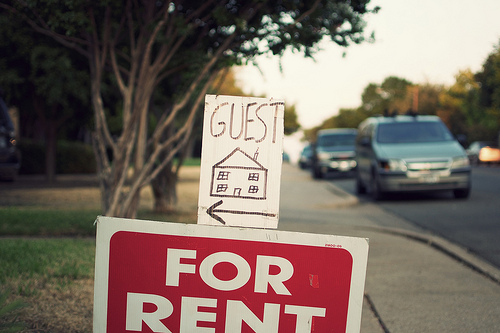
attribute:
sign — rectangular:
[197, 91, 297, 223]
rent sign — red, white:
[96, 212, 378, 331]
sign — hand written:
[174, 90, 401, 211]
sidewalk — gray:
[262, 166, 463, 328]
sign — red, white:
[32, 187, 394, 332]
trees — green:
[31, 10, 241, 232]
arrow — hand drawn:
[199, 194, 281, 226]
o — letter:
[199, 242, 250, 291]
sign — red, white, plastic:
[88, 214, 375, 331]